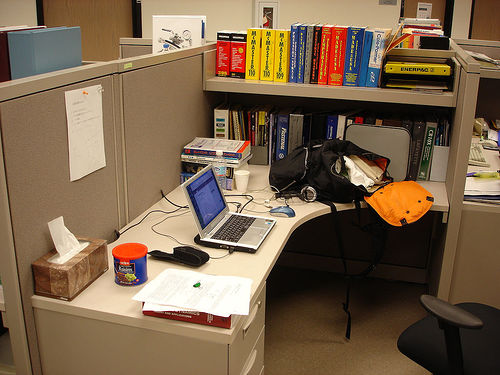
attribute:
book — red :
[323, 22, 344, 89]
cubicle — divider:
[10, 150, 457, 374]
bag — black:
[267, 137, 434, 227]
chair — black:
[403, 286, 493, 366]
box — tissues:
[29, 235, 111, 310]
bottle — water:
[205, 145, 225, 180]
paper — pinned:
[58, 80, 116, 187]